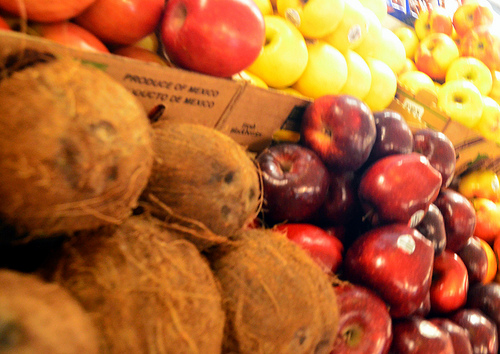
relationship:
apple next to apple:
[256, 95, 495, 351] [302, 94, 375, 172]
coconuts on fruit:
[7, 58, 344, 352] [11, 1, 493, 343]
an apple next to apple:
[302, 101, 384, 165] [242, 139, 370, 224]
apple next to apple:
[336, 283, 391, 352] [351, 215, 448, 304]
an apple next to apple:
[302, 101, 384, 165] [394, 194, 453, 255]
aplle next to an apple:
[161, 0, 264, 79] [302, 101, 384, 165]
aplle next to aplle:
[255, 142, 331, 222] [357, 147, 444, 228]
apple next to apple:
[256, 95, 495, 351] [410, 115, 454, 179]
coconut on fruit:
[2, 52, 162, 252] [11, 1, 500, 354]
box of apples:
[229, 86, 314, 149] [303, 22, 413, 84]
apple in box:
[163, 0, 265, 73] [6, 30, 311, 146]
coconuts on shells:
[7, 58, 344, 352] [211, 225, 336, 352]